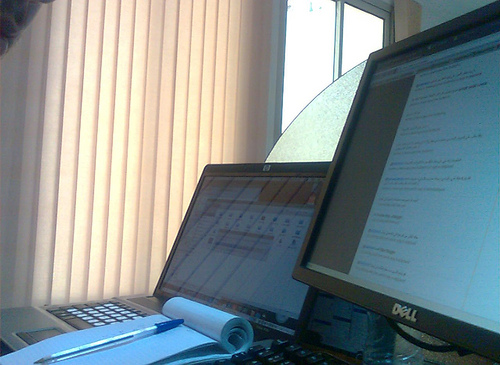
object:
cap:
[153, 318, 184, 335]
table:
[0, 321, 500, 365]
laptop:
[0, 163, 332, 364]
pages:
[0, 314, 221, 365]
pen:
[34, 317, 189, 364]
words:
[388, 213, 402, 221]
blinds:
[0, 0, 283, 310]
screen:
[301, 14, 500, 333]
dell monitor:
[291, 0, 500, 365]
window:
[279, 0, 342, 132]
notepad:
[0, 297, 256, 365]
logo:
[390, 302, 419, 323]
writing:
[352, 53, 487, 285]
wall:
[0, 0, 286, 309]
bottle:
[365, 307, 428, 365]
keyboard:
[206, 335, 348, 365]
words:
[378, 248, 396, 256]